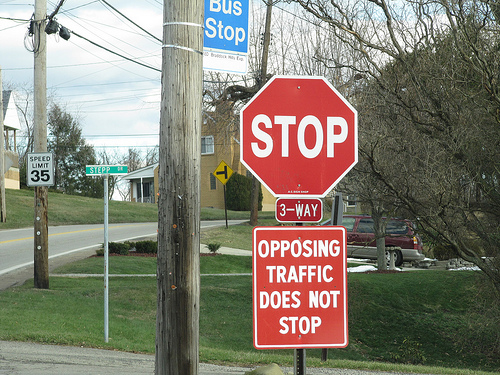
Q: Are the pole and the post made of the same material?
A: No, the pole is made of wood and the post is made of metal.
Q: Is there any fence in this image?
A: No, there are no fences.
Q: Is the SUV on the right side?
A: Yes, the SUV is on the right of the image.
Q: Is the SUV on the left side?
A: No, the SUV is on the right of the image.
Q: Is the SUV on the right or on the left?
A: The SUV is on the right of the image.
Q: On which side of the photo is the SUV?
A: The SUV is on the right of the image.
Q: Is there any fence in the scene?
A: No, there are no fences.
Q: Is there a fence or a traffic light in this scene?
A: No, there are no fences or traffic lights.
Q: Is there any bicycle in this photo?
A: No, there are no bicycles.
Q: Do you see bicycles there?
A: No, there are no bicycles.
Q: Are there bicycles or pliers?
A: No, there are no bicycles or pliers.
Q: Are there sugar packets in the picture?
A: No, there are no sugar packets.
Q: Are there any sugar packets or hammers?
A: No, there are no sugar packets or hammers.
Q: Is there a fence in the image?
A: No, there are no fences.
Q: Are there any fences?
A: No, there are no fences.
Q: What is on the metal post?
A: The sign is on the post.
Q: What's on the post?
A: The sign is on the post.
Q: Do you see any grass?
A: Yes, there is grass.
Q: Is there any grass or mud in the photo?
A: Yes, there is grass.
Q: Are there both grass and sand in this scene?
A: No, there is grass but no sand.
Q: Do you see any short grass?
A: Yes, there is short grass.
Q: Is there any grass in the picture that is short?
A: Yes, there is grass that is short.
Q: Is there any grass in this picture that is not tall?
A: Yes, there is short grass.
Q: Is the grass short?
A: Yes, the grass is short.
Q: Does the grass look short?
A: Yes, the grass is short.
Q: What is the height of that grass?
A: The grass is short.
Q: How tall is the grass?
A: The grass is short.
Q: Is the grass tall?
A: No, the grass is short.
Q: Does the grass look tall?
A: No, the grass is short.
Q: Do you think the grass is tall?
A: No, the grass is short.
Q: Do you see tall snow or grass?
A: No, there is grass but it is short.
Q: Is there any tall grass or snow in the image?
A: No, there is grass but it is short.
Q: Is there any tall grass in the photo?
A: No, there is grass but it is short.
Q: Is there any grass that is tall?
A: No, there is grass but it is short.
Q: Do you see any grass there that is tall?
A: No, there is grass but it is short.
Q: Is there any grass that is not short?
A: No, there is grass but it is short.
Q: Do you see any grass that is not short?
A: No, there is grass but it is short.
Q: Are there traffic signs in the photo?
A: Yes, there is a traffic sign.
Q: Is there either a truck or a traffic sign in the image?
A: Yes, there is a traffic sign.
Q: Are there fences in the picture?
A: No, there are no fences.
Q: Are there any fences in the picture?
A: No, there are no fences.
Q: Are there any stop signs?
A: Yes, there is a stop sign.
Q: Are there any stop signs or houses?
A: Yes, there is a stop sign.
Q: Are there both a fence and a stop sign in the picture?
A: No, there is a stop sign but no fences.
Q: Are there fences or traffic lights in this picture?
A: No, there are no fences or traffic lights.